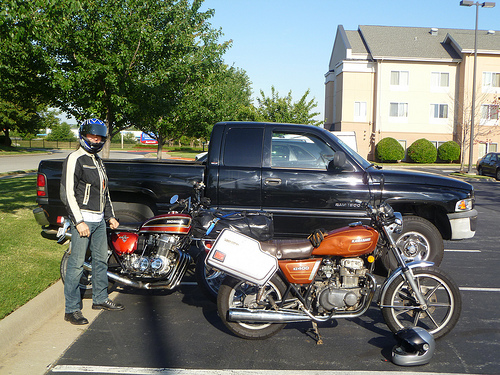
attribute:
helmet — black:
[75, 112, 107, 153]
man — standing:
[74, 123, 128, 313]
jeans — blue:
[73, 232, 109, 289]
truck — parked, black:
[214, 123, 460, 213]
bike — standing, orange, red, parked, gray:
[244, 232, 460, 324]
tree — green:
[129, 29, 200, 91]